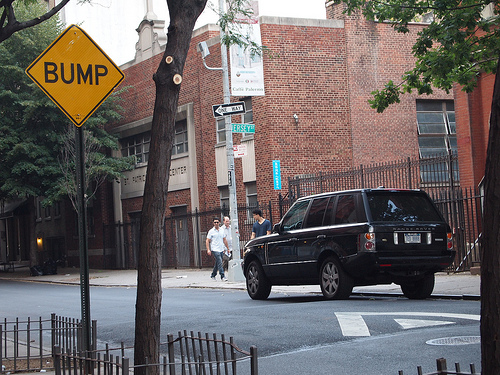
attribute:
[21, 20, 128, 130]
sign — yellow, road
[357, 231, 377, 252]
taillight — back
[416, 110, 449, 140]
windows — open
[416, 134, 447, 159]
windows — open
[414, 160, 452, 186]
windows — open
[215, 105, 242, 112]
sign — yellow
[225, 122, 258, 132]
sign — yellow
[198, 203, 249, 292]
people — talking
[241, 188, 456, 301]
vehicle — parked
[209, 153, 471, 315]
vehicle — black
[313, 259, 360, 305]
wheel — back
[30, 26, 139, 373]
post — green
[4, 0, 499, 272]
brick building — red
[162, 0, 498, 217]
building —  bricks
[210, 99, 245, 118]
sign — traffic, one way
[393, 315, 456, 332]
line — white, triangular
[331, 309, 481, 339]
line — white, triangular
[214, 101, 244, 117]
arrow — white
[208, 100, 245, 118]
square — black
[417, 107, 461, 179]
windows — slightly open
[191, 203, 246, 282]
people — group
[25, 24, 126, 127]
sign — hazard, yellow, diamond shaped, black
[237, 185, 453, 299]
suv — clean, black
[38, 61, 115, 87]
word — bump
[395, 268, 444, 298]
wheel — back